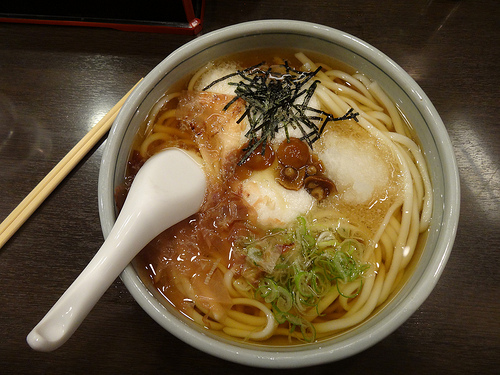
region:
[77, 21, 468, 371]
Food in a bowl.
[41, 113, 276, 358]
Spoon in the bowl.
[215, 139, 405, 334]
Green onions in the soup.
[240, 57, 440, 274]
Noodles in the bowl.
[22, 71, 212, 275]
Chopsticks on the table.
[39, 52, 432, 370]
Wood table under bowl.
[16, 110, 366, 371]
Ceramic spoon in the bowl.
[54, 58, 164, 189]
Shine on the table.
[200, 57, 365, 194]
Vegetables on the soup.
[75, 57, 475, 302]
Soup with vegetables in the bowl.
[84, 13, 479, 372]
a white bowl of soup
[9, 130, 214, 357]
chinese spoon on a bowl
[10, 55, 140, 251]
two chinese sticks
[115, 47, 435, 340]
chinese noodle soup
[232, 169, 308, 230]
white cream in soup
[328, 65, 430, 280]
noodles in soup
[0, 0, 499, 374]
a dark brown table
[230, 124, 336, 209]
mushrooms on top of soup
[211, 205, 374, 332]
green vegetables on soup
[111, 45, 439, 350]
soup is brown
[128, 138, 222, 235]
White spoon in a bowl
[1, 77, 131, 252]
Chop sticks on a table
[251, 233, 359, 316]
Green vegetable in a soup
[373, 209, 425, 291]
Noodles in a soup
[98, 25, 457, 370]
White bowl on a table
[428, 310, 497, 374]
Brown wooden table top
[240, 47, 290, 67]
Brown broth of a soup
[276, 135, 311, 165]
Brown mushrooms in a soup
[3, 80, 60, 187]
Reflection of glass on a table top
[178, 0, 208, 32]
Red corner of a tray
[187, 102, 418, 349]
a bowl of ramen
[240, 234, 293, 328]
a bowl of ramen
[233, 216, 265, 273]
a bowl of ramen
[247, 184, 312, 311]
a bowl of ramen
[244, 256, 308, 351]
a bowl of ramen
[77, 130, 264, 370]
the spoon is white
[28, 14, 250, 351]
the spoon is white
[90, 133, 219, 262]
the spoon is white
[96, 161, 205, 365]
the spoon is white